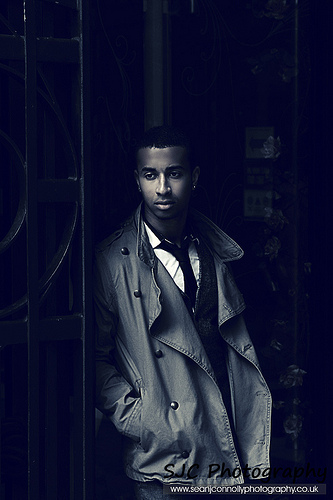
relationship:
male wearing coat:
[93, 106, 276, 498] [96, 203, 273, 486]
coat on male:
[82, 196, 276, 486] [93, 106, 276, 498]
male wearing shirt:
[93, 106, 276, 498] [139, 218, 206, 311]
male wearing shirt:
[93, 106, 276, 498] [147, 227, 204, 291]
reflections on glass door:
[234, 105, 297, 291] [196, 12, 323, 438]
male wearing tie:
[93, 106, 276, 498] [152, 234, 202, 309]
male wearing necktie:
[93, 106, 276, 498] [156, 234, 199, 312]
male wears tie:
[93, 106, 276, 498] [159, 238, 199, 301]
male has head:
[85, 106, 267, 472] [117, 120, 222, 250]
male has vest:
[93, 106, 276, 498] [162, 220, 234, 422]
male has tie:
[93, 106, 276, 498] [155, 239, 196, 302]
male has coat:
[93, 106, 276, 498] [82, 196, 276, 486]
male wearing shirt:
[93, 106, 276, 498] [141, 220, 199, 308]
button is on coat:
[170, 402, 181, 411] [96, 203, 273, 486]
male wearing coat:
[93, 106, 276, 498] [82, 196, 276, 486]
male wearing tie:
[93, 106, 276, 498] [154, 235, 198, 308]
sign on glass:
[232, 115, 295, 223] [205, 64, 298, 236]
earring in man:
[187, 184, 206, 195] [111, 138, 304, 381]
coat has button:
[96, 203, 273, 486] [115, 241, 132, 256]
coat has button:
[96, 203, 273, 486] [128, 284, 145, 303]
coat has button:
[96, 203, 273, 486] [149, 346, 168, 363]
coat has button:
[96, 203, 273, 486] [165, 398, 183, 412]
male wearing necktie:
[93, 106, 276, 498] [160, 240, 199, 312]